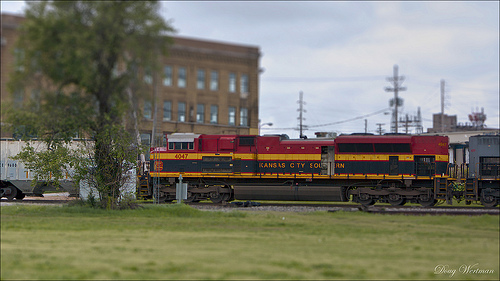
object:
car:
[148, 131, 500, 208]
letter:
[259, 163, 263, 168]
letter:
[278, 162, 286, 168]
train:
[148, 133, 500, 208]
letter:
[263, 163, 268, 168]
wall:
[0, 32, 258, 200]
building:
[0, 11, 497, 198]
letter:
[258, 162, 346, 169]